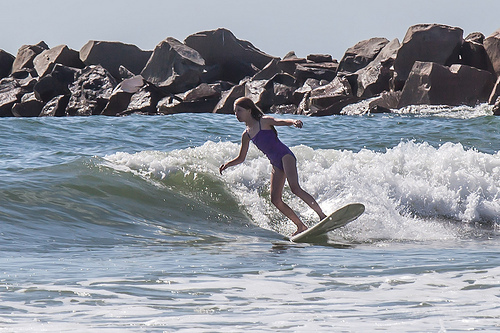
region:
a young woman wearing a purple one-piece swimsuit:
[206, 95, 374, 252]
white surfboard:
[250, 200, 370, 255]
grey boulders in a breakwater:
[1, 12, 436, 117]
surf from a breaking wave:
[326, 130, 496, 230]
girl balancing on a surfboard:
[212, 90, 372, 245]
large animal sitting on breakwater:
[110, 60, 142, 89]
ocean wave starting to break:
[1, 140, 224, 246]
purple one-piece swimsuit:
[245, 123, 295, 183]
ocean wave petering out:
[3, 241, 493, 326]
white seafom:
[282, 275, 499, 330]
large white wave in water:
[358, 145, 449, 195]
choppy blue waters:
[10, 120, 127, 205]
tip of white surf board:
[318, 198, 385, 227]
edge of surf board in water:
[272, 225, 317, 260]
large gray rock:
[130, 30, 205, 97]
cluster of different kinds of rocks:
[4, 24, 499, 151]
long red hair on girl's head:
[231, 90, 281, 118]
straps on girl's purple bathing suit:
[241, 121, 271, 136]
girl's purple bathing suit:
[227, 127, 322, 172]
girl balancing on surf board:
[173, 76, 358, 281]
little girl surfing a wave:
[215, 90, 370, 252]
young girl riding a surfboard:
[213, 92, 374, 248]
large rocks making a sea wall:
[5, 28, 205, 133]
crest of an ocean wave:
[19, 123, 193, 324]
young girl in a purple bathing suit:
[211, 92, 323, 199]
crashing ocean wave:
[367, 118, 498, 248]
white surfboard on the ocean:
[260, 195, 371, 255]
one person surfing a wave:
[209, 91, 411, 295]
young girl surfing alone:
[93, 78, 414, 288]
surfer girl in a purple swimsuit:
[196, 87, 379, 255]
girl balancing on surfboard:
[165, 60, 372, 255]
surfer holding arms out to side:
[210, 85, 360, 250]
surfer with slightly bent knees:
[210, 85, 345, 255]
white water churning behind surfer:
[192, 125, 458, 240]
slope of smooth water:
[11, 140, 206, 265]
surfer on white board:
[275, 190, 380, 246]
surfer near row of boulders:
[21, 20, 471, 121]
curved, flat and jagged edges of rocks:
[40, 40, 185, 100]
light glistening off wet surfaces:
[50, 60, 195, 116]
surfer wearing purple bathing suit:
[205, 81, 325, 241]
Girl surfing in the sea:
[205, 85, 361, 251]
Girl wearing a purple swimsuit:
[205, 77, 341, 234]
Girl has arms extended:
[208, 93, 336, 236]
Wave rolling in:
[50, 129, 495, 268]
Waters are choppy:
[33, 136, 499, 293]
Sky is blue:
[0, 0, 495, 49]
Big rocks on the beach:
[1, 14, 499, 112]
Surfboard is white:
[271, 198, 373, 245]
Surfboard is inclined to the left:
[205, 79, 341, 243]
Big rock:
[129, 34, 216, 101]